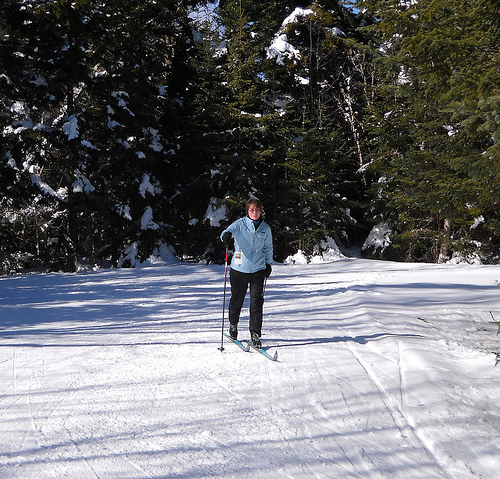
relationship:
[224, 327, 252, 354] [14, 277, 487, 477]
her skis traversing trail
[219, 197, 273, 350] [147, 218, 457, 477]
person on snow trail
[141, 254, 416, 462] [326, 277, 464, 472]
snow trail in snow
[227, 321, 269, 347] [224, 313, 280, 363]
boots strapped into skies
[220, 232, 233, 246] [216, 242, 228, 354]
hand holding pole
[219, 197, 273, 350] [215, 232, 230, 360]
person holding pole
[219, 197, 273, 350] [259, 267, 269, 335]
person holding pole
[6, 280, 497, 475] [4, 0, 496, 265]
snow covered fir trees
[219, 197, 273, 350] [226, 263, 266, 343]
person wearing black pants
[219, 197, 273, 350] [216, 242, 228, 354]
person holding pole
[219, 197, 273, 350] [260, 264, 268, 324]
person holding pole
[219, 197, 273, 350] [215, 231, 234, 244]
person wearing glove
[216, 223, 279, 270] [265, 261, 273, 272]
gloves wearing glove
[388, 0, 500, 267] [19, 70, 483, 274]
fir trees in background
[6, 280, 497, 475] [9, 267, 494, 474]
snow covering ground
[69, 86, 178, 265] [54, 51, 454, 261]
snow covering trees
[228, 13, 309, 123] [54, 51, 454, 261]
snow covering trees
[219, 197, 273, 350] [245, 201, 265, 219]
person has hair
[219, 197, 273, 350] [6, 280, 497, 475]
person skiing in snow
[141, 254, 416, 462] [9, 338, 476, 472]
snow trail in snow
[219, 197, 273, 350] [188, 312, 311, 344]
person has her skis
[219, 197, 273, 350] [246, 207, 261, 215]
person wearing glasses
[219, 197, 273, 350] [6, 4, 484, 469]
person up in mountains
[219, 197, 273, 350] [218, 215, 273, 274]
person wearing jacket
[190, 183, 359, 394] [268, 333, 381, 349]
person casting shadow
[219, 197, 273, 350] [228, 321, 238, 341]
person wearing boot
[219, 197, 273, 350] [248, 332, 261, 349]
person wearing boot